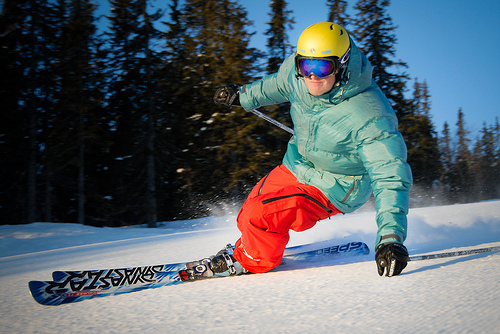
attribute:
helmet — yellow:
[296, 19, 353, 59]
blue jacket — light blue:
[238, 35, 414, 244]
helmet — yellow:
[293, 20, 347, 57]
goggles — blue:
[297, 54, 334, 76]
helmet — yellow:
[292, 18, 353, 80]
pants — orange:
[231, 162, 339, 272]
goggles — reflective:
[293, 55, 340, 75]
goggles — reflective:
[283, 50, 358, 84]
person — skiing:
[204, 21, 416, 281]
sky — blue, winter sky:
[415, 28, 495, 81]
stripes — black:
[235, 162, 380, 296]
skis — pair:
[28, 267, 202, 306]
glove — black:
[375, 241, 407, 276]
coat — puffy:
[236, 45, 414, 246]